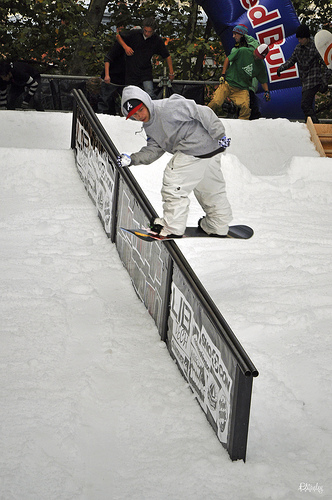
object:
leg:
[193, 153, 233, 237]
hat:
[254, 43, 269, 59]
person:
[208, 44, 271, 120]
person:
[277, 23, 330, 124]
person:
[116, 15, 174, 99]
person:
[230, 23, 261, 121]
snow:
[0, 110, 332, 500]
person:
[98, 30, 145, 115]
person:
[0, 58, 41, 111]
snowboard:
[314, 30, 331, 71]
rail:
[39, 72, 221, 85]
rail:
[70, 88, 259, 378]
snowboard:
[118, 225, 253, 243]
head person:
[142, 15, 156, 38]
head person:
[232, 23, 248, 43]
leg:
[208, 81, 230, 111]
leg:
[229, 88, 252, 120]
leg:
[161, 151, 207, 235]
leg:
[143, 80, 157, 100]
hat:
[123, 99, 144, 121]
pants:
[160, 151, 233, 236]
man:
[116, 84, 233, 238]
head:
[120, 85, 155, 126]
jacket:
[120, 85, 226, 167]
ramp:
[71, 88, 261, 465]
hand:
[116, 153, 131, 167]